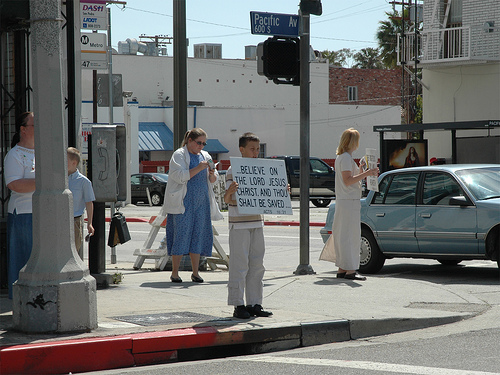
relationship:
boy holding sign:
[224, 132, 293, 319] [223, 152, 294, 219]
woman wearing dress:
[158, 121, 216, 292] [167, 146, 223, 251]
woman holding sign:
[319, 128, 380, 281] [363, 144, 380, 192]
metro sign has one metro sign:
[80, 3, 108, 70] [65, 2, 111, 57]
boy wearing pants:
[224, 132, 293, 319] [217, 207, 283, 325]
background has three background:
[376, 182, 487, 324] [130, 155, 500, 273]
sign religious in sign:
[226, 153, 296, 216] [229, 156, 293, 215]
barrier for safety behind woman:
[146, 213, 226, 271] [158, 128, 225, 283]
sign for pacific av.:
[250, 9, 304, 39] [254, 50, 266, 58]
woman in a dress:
[319, 128, 380, 281] [318, 152, 365, 272]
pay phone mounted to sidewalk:
[82, 111, 135, 230] [85, 241, 220, 345]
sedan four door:
[320, 162, 499, 272] [397, 187, 463, 230]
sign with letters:
[250, 11, 299, 37] [252, 13, 300, 33]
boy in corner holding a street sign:
[222, 134, 282, 311] [206, 155, 315, 220]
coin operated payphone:
[95, 134, 108, 197] [88, 124, 128, 291]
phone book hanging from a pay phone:
[106, 207, 132, 249] [84, 123, 129, 200]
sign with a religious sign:
[229, 156, 293, 215] [229, 156, 293, 215]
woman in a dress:
[158, 128, 225, 283] [168, 141, 218, 270]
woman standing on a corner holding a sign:
[330, 129, 381, 282] [361, 142, 381, 192]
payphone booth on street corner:
[96, 120, 127, 288] [298, 273, 465, 337]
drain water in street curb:
[179, 338, 263, 362] [0, 320, 350, 374]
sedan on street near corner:
[320, 164, 500, 275] [430, 274, 475, 364]